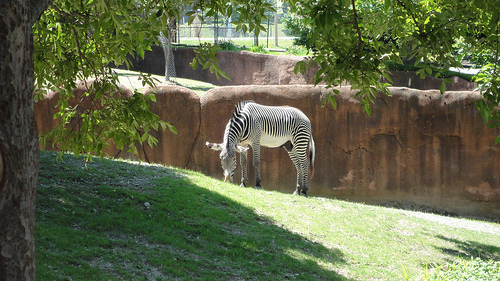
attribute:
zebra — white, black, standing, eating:
[223, 96, 313, 167]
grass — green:
[134, 199, 309, 262]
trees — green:
[147, 5, 195, 79]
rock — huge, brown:
[355, 115, 440, 178]